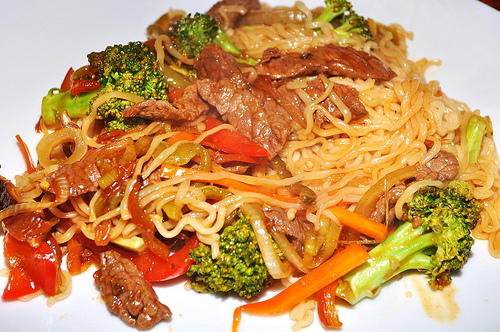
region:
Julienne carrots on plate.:
[235, 240, 371, 326]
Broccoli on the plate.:
[186, 211, 266, 301]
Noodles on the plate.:
[277, 76, 427, 162]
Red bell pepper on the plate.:
[5, 212, 62, 302]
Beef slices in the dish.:
[200, 40, 332, 137]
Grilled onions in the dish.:
[11, 165, 66, 215]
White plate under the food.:
[1, 0, 496, 325]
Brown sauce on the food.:
[55, 2, 465, 282]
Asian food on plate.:
[2, 3, 498, 322]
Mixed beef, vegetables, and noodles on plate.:
[27, 10, 494, 326]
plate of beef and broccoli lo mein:
[4, 2, 494, 324]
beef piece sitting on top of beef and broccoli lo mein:
[257, 48, 394, 80]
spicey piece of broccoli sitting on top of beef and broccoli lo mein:
[87, 38, 164, 120]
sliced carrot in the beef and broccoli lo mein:
[229, 243, 374, 313]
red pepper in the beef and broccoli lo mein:
[2, 228, 74, 292]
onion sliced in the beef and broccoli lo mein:
[37, 125, 86, 166]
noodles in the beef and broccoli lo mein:
[326, 81, 458, 163]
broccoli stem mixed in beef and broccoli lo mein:
[41, 89, 101, 123]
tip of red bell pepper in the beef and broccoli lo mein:
[217, 131, 269, 158]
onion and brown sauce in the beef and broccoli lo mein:
[16, 141, 133, 212]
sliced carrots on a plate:
[178, 188, 405, 323]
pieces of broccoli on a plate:
[191, 172, 472, 312]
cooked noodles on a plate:
[281, 90, 442, 254]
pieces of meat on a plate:
[193, 46, 343, 148]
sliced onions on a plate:
[0, 149, 119, 276]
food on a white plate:
[0, 33, 472, 328]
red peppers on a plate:
[15, 213, 221, 308]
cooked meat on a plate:
[138, 39, 378, 161]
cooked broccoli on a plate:
[178, 176, 476, 319]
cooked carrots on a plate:
[266, 192, 404, 307]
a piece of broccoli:
[331, 179, 486, 328]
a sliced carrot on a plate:
[229, 183, 394, 330]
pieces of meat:
[142, 41, 373, 141]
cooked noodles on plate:
[192, 85, 446, 242]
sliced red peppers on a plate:
[4, 234, 234, 309]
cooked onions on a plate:
[0, 101, 147, 264]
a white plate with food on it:
[28, 12, 484, 330]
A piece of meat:
[90, 241, 171, 331]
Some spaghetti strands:
[137, 162, 228, 240]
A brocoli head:
[415, 184, 474, 295]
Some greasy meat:
[251, 37, 393, 79]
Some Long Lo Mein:
[343, 93, 408, 166]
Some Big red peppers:
[0, 230, 66, 321]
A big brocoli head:
[200, 216, 271, 293]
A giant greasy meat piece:
[193, 41, 308, 167]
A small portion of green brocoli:
[452, 90, 497, 192]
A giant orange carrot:
[230, 239, 367, 329]